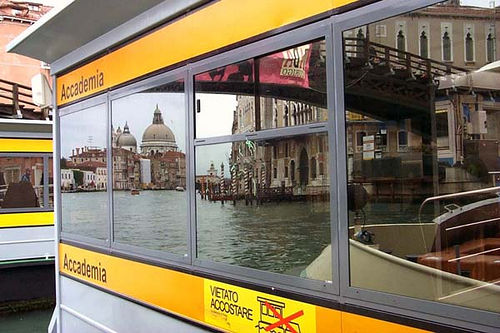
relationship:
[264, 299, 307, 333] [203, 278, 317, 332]
x on sign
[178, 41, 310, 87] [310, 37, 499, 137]
banner hanging on bridge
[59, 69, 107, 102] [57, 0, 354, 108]
writing on background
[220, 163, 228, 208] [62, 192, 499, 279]
pole sticking out of water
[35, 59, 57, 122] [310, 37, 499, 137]
person by bridge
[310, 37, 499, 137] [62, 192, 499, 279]
bridge over water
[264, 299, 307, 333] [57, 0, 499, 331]
x under window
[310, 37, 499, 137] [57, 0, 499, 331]
bridge reflects on window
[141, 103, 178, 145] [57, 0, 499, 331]
dome reflecting on window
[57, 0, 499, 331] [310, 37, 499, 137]
window above a bridge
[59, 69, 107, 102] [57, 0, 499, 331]
writing on top of window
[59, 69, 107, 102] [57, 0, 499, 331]
writing above window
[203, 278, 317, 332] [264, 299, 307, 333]
sign next to an x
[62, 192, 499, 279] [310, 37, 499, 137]
water under a bridge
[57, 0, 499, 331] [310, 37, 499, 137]
window by a bridge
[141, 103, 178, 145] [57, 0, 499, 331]
dome in window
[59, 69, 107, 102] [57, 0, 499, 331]
writing over a window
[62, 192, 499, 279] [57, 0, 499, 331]
water in window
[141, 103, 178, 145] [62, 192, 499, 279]
dome over water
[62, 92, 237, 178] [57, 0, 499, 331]
sky in window